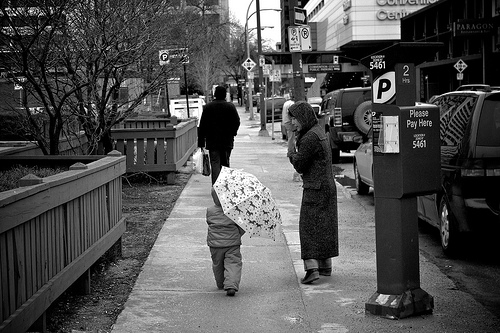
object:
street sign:
[294, 7, 308, 26]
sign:
[241, 58, 257, 72]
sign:
[268, 70, 282, 82]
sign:
[159, 48, 190, 66]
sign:
[454, 59, 468, 74]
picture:
[0, 0, 498, 332]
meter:
[358, 41, 443, 321]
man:
[197, 85, 240, 187]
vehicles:
[256, 97, 286, 123]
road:
[333, 163, 499, 319]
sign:
[287, 23, 313, 53]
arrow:
[291, 47, 299, 50]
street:
[260, 62, 497, 300]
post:
[107, 150, 122, 157]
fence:
[2, 149, 127, 332]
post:
[69, 162, 88, 169]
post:
[15, 173, 43, 188]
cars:
[353, 84, 500, 259]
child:
[206, 187, 246, 297]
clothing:
[196, 99, 240, 149]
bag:
[192, 148, 210, 177]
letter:
[377, 79, 391, 100]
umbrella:
[213, 165, 286, 241]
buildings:
[259, 0, 497, 123]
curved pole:
[244, 0, 275, 141]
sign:
[373, 71, 396, 104]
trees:
[0, 0, 273, 155]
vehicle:
[319, 87, 371, 164]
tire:
[354, 100, 373, 134]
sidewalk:
[114, 98, 497, 332]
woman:
[287, 100, 338, 284]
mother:
[287, 100, 339, 283]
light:
[240, 0, 281, 130]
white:
[226, 0, 283, 50]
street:
[245, 102, 500, 322]